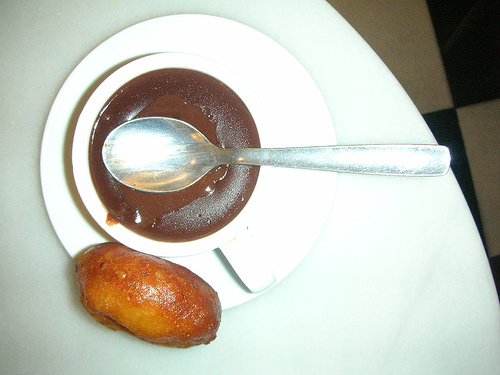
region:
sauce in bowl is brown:
[78, 70, 285, 254]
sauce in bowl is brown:
[72, 67, 382, 322]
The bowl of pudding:
[68, 48, 267, 257]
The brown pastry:
[74, 240, 231, 354]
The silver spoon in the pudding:
[98, 113, 457, 195]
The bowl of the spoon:
[99, 111, 214, 197]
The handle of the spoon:
[221, 138, 453, 181]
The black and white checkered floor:
[328, 0, 499, 302]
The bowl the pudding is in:
[69, 49, 267, 259]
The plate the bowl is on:
[33, 10, 340, 311]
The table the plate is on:
[0, 0, 497, 374]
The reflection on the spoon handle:
[293, 146, 443, 173]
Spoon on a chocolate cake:
[100, 117, 220, 187]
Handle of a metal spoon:
[226, 142, 456, 175]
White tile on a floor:
[333, 1, 455, 117]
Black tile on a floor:
[424, 0, 499, 107]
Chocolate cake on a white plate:
[64, 66, 274, 247]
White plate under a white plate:
[36, 12, 335, 302]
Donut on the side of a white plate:
[74, 242, 228, 352]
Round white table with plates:
[4, 4, 498, 373]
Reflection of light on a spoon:
[112, 127, 184, 169]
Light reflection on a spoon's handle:
[312, 146, 438, 170]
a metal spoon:
[98, 117, 455, 197]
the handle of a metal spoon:
[229, 141, 456, 181]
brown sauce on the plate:
[85, 66, 264, 248]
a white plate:
[37, 7, 345, 327]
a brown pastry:
[71, 235, 227, 351]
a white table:
[1, 0, 498, 371]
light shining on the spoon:
[118, 127, 184, 170]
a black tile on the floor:
[425, 0, 499, 114]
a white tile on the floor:
[327, 0, 459, 116]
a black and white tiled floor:
[327, 0, 499, 297]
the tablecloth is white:
[355, 260, 403, 312]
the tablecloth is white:
[350, 276, 410, 341]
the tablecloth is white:
[306, 281, 376, 352]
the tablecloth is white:
[330, 305, 391, 359]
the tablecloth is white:
[305, 281, 343, 311]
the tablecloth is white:
[350, 322, 385, 347]